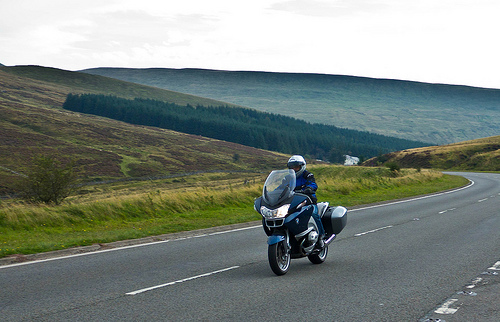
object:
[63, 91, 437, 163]
trees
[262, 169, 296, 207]
windshield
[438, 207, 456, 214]
line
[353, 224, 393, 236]
line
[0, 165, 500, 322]
highway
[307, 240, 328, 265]
tire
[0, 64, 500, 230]
hill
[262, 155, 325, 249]
man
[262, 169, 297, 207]
window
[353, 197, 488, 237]
stripe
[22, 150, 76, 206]
bush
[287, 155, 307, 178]
helmet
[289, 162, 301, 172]
head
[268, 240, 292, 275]
tire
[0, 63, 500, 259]
grass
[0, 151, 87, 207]
tree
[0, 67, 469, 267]
field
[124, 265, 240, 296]
line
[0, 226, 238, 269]
edge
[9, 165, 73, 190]
leaves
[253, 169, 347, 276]
bike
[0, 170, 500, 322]
road